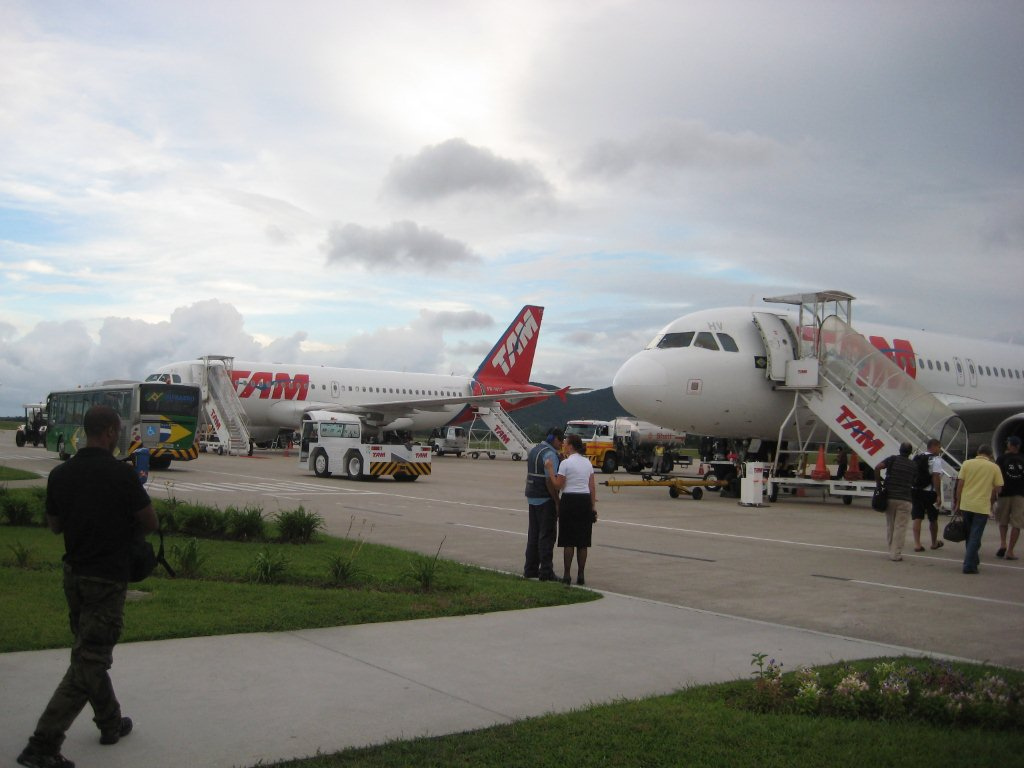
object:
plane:
[610, 288, 1023, 516]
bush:
[271, 505, 329, 546]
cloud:
[383, 139, 558, 222]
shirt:
[47, 448, 159, 584]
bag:
[942, 515, 967, 543]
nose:
[610, 351, 727, 420]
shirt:
[556, 454, 594, 494]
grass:
[243, 653, 1023, 765]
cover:
[525, 268, 701, 413]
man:
[953, 444, 1003, 578]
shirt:
[956, 458, 1003, 517]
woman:
[548, 427, 598, 585]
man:
[873, 440, 920, 562]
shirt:
[877, 455, 916, 503]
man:
[16, 406, 159, 766]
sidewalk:
[0, 582, 967, 765]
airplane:
[140, 304, 591, 462]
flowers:
[733, 655, 1024, 735]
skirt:
[556, 492, 597, 548]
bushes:
[176, 499, 263, 544]